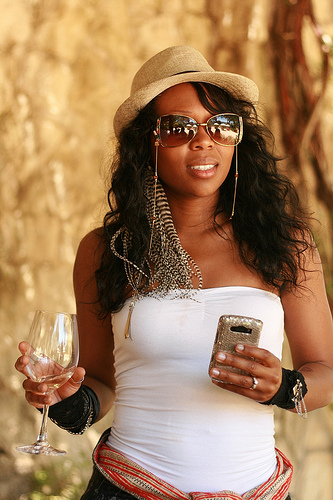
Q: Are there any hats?
A: Yes, there is a hat.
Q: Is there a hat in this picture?
A: Yes, there is a hat.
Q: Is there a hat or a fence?
A: Yes, there is a hat.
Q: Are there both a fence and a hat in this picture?
A: No, there is a hat but no fences.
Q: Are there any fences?
A: No, there are no fences.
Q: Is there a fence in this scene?
A: No, there are no fences.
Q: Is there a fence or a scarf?
A: No, there are no fences or scarves.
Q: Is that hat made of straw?
A: Yes, the hat is made of straw.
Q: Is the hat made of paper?
A: No, the hat is made of straw.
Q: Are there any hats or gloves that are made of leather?
A: No, there is a hat but it is made of straw.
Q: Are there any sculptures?
A: No, there are no sculptures.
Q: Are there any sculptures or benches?
A: No, there are no sculptures or benches.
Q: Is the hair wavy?
A: Yes, the hair is wavy.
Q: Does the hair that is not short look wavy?
A: Yes, the hair is wavy.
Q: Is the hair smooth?
A: No, the hair is wavy.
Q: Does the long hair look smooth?
A: No, the hair is wavy.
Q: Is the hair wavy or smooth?
A: The hair is wavy.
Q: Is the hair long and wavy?
A: Yes, the hair is long and wavy.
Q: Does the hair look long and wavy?
A: Yes, the hair is long and wavy.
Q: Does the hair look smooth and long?
A: No, the hair is long but wavy.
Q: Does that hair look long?
A: Yes, the hair is long.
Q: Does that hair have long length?
A: Yes, the hair is long.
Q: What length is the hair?
A: The hair is long.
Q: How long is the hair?
A: The hair is long.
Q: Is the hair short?
A: No, the hair is long.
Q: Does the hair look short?
A: No, the hair is long.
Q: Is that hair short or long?
A: The hair is long.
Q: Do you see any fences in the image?
A: No, there are no fences.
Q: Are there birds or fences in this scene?
A: No, there are no fences or birds.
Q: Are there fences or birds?
A: No, there are no fences or birds.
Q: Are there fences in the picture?
A: No, there are no fences.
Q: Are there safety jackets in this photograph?
A: No, there are no safety jackets.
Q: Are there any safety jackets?
A: No, there are no safety jackets.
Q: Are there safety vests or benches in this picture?
A: No, there are no safety vests or benches.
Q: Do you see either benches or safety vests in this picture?
A: No, there are no safety vests or benches.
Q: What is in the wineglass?
A: The liquid is in the wineglass.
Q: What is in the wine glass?
A: The liquid is in the wineglass.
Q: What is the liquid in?
A: The liquid is in the wineglass.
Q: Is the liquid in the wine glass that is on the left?
A: Yes, the liquid is in the wine glass.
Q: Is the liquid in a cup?
A: No, the liquid is in the wine glass.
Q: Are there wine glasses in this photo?
A: Yes, there is a wine glass.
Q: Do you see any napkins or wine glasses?
A: Yes, there is a wine glass.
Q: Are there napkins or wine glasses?
A: Yes, there is a wine glass.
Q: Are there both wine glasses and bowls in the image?
A: No, there is a wine glass but no bowls.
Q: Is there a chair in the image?
A: No, there are no chairs.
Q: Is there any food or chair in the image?
A: No, there are no chairs or food.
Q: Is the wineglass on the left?
A: Yes, the wineglass is on the left of the image.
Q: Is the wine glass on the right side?
A: No, the wine glass is on the left of the image.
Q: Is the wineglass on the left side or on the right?
A: The wineglass is on the left of the image.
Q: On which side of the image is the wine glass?
A: The wine glass is on the left of the image.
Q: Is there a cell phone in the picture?
A: Yes, there is a cell phone.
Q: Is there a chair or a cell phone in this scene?
A: Yes, there is a cell phone.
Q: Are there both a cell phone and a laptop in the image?
A: No, there is a cell phone but no laptops.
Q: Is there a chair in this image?
A: No, there are no chairs.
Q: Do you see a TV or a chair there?
A: No, there are no chairs or televisions.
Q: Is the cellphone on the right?
A: Yes, the cellphone is on the right of the image.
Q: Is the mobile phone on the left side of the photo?
A: No, the mobile phone is on the right of the image.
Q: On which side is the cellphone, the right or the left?
A: The cellphone is on the right of the image.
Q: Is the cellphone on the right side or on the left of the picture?
A: The cellphone is on the right of the image.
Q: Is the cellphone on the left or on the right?
A: The cellphone is on the right of the image.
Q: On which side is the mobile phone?
A: The mobile phone is on the right of the image.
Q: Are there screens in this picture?
A: No, there are no screens.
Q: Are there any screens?
A: No, there are no screens.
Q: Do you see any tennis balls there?
A: No, there are no tennis balls.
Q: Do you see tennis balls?
A: No, there are no tennis balls.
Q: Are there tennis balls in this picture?
A: No, there are no tennis balls.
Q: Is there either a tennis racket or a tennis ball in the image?
A: No, there are no tennis balls or rackets.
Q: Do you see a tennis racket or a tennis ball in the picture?
A: No, there are no tennis balls or rackets.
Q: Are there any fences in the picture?
A: No, there are no fences.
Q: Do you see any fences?
A: No, there are no fences.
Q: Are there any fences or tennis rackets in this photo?
A: No, there are no fences or tennis rackets.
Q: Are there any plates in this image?
A: No, there are no plates.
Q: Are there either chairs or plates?
A: No, there are no plates or chairs.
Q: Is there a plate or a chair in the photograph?
A: No, there are no plates or chairs.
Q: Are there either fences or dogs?
A: No, there are no fences or dogs.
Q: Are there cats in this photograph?
A: No, there are no cats.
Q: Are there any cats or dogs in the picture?
A: No, there are no cats or dogs.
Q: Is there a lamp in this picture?
A: No, there are no lamps.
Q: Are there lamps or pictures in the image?
A: No, there are no lamps or pictures.